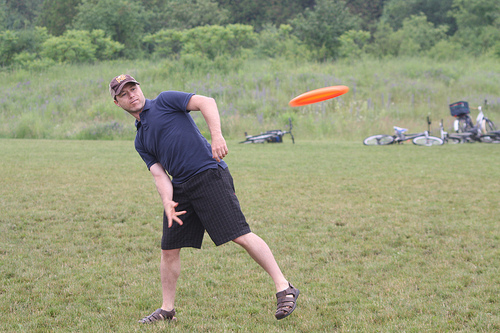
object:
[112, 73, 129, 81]
branding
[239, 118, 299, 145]
bicycles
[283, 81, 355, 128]
frisbee air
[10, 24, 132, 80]
tree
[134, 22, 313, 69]
tree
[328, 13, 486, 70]
tree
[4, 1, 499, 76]
bush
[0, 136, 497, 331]
grass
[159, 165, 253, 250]
black shorts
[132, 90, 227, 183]
blue shirt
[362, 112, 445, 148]
bicycle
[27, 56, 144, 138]
unkept grass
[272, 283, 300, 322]
sandals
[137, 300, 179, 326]
sandals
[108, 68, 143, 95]
cap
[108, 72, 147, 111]
head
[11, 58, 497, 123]
grass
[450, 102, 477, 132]
bicycle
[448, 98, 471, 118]
blue box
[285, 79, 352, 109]
frisbee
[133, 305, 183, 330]
foot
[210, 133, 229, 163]
hand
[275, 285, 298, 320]
foot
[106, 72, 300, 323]
man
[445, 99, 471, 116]
bike seat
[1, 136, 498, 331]
field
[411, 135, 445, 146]
bicycle wheel